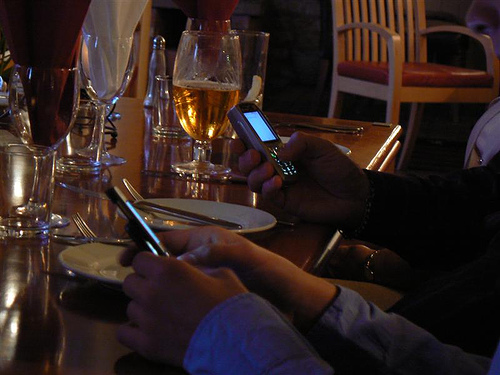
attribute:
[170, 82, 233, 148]
wine — gold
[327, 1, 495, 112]
chair — empty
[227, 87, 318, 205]
phone — silver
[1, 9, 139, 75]
napkin — white, red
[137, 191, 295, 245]
plate — white